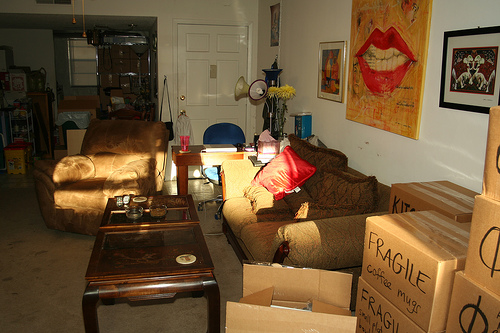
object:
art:
[318, 40, 346, 103]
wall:
[294, 20, 303, 73]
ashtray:
[150, 202, 167, 214]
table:
[86, 228, 223, 329]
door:
[180, 23, 244, 149]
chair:
[34, 117, 163, 235]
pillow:
[254, 148, 323, 198]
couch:
[221, 139, 403, 259]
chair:
[200, 124, 245, 216]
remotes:
[113, 191, 136, 211]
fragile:
[366, 232, 436, 289]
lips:
[355, 31, 414, 92]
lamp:
[248, 81, 273, 105]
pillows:
[307, 161, 374, 214]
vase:
[29, 63, 50, 93]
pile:
[8, 147, 30, 178]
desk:
[172, 127, 301, 195]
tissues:
[257, 137, 296, 156]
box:
[258, 139, 280, 159]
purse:
[167, 87, 177, 148]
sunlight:
[267, 162, 295, 201]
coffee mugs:
[363, 263, 432, 317]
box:
[364, 209, 483, 331]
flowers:
[280, 85, 290, 95]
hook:
[165, 72, 168, 89]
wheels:
[210, 214, 227, 221]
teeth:
[373, 54, 377, 64]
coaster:
[180, 254, 200, 264]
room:
[28, 54, 347, 308]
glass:
[115, 209, 189, 220]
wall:
[432, 127, 480, 180]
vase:
[267, 108, 292, 137]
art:
[441, 25, 500, 110]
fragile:
[354, 291, 397, 332]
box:
[355, 269, 426, 331]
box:
[225, 261, 358, 331]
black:
[369, 231, 376, 249]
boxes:
[476, 108, 500, 198]